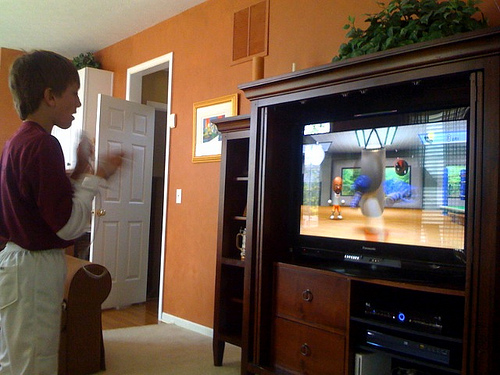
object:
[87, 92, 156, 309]
door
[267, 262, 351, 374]
drawers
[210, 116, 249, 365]
book shelf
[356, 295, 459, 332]
dvd player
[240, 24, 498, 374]
stand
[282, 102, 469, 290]
tv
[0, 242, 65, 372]
pants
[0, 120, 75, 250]
shirt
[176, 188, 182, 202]
light switch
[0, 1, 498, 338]
wall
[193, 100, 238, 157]
picture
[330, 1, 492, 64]
plant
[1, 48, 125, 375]
boy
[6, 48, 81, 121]
hair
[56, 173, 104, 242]
sleeve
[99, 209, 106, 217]
door knob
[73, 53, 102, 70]
plant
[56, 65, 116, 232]
cabinet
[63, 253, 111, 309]
arm of sofa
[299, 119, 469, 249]
video game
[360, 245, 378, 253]
name brand